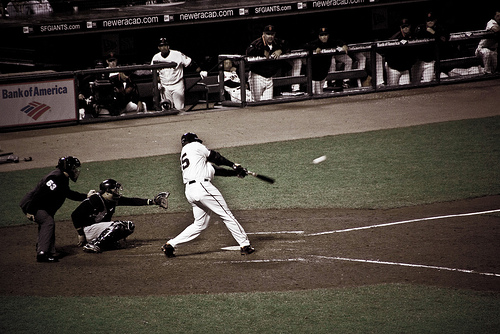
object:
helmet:
[54, 156, 83, 183]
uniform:
[164, 142, 249, 247]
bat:
[244, 168, 276, 184]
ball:
[309, 155, 328, 163]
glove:
[234, 168, 247, 178]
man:
[71, 178, 172, 253]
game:
[0, 0, 499, 333]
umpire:
[19, 155, 97, 263]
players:
[150, 36, 209, 113]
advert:
[0, 78, 77, 126]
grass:
[292, 138, 488, 195]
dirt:
[129, 259, 240, 279]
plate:
[240, 243, 257, 254]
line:
[303, 208, 499, 237]